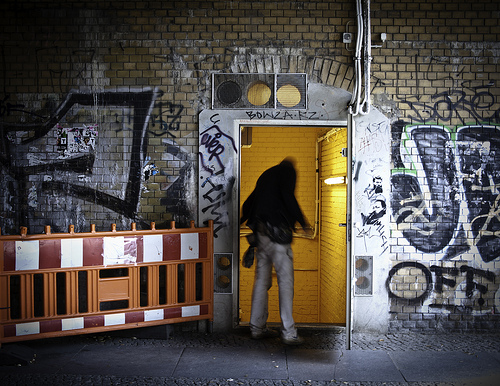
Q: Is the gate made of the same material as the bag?
A: Yes, both the gate and the bag are made of plastic.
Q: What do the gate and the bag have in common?
A: The material, both the gate and the bag are plastic.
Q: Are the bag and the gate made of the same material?
A: Yes, both the bag and the gate are made of plastic.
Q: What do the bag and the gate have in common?
A: The material, both the bag and the gate are plastic.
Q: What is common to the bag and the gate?
A: The material, both the bag and the gate are plastic.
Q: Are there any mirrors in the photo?
A: No, there are no mirrors.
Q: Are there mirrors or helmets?
A: No, there are no mirrors or helmets.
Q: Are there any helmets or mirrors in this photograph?
A: No, there are no mirrors or helmets.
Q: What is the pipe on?
A: The pipe is on the wall.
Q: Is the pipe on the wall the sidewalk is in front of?
A: Yes, the pipe is on the wall.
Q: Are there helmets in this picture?
A: No, there are no helmets.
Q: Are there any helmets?
A: No, there are no helmets.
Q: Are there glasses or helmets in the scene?
A: No, there are no helmets or glasses.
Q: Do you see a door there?
A: Yes, there is a door.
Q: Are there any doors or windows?
A: Yes, there is a door.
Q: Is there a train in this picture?
A: No, there are no trains.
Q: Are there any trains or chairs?
A: No, there are no trains or chairs.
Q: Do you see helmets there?
A: No, there are no helmets.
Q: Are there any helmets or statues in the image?
A: No, there are no helmets or statues.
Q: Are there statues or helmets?
A: No, there are no helmets or statues.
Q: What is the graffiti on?
A: The graffiti is on the wall.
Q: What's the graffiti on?
A: The graffiti is on the wall.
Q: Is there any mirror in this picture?
A: No, there are no mirrors.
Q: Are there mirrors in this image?
A: No, there are no mirrors.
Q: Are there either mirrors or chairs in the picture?
A: No, there are no mirrors or chairs.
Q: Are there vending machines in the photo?
A: No, there are no vending machines.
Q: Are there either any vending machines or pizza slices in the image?
A: No, there are no vending machines or pizza slices.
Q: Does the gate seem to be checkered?
A: Yes, the gate is checkered.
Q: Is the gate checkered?
A: Yes, the gate is checkered.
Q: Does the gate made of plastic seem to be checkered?
A: Yes, the gate is checkered.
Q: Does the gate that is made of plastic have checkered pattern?
A: Yes, the gate is checkered.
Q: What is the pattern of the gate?
A: The gate is checkered.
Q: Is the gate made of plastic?
A: Yes, the gate is made of plastic.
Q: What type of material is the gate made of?
A: The gate is made of plastic.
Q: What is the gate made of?
A: The gate is made of plastic.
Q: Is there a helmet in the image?
A: No, there are no helmets.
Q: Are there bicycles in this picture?
A: No, there are no bicycles.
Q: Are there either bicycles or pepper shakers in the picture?
A: No, there are no bicycles or pepper shakers.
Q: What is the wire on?
A: The wire is on the wall.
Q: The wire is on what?
A: The wire is on the wall.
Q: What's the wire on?
A: The wire is on the wall.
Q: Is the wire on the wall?
A: Yes, the wire is on the wall.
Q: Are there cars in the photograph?
A: No, there are no cars.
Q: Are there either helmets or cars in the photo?
A: No, there are no cars or helmets.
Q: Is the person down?
A: Yes, the person is down.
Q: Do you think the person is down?
A: Yes, the person is down.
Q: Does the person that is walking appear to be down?
A: Yes, the person is down.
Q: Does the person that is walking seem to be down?
A: Yes, the person is down.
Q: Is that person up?
A: No, the person is down.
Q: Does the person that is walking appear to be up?
A: No, the person is down.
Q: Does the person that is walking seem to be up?
A: No, the person is down.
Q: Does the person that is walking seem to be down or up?
A: The person is down.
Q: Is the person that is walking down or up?
A: The person is down.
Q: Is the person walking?
A: Yes, the person is walking.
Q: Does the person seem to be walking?
A: Yes, the person is walking.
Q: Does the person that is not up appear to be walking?
A: Yes, the person is walking.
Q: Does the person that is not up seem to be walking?
A: Yes, the person is walking.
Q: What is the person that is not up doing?
A: The person is walking.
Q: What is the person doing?
A: The person is walking.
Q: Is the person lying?
A: No, the person is walking.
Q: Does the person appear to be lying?
A: No, the person is walking.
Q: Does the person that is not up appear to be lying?
A: No, the person is walking.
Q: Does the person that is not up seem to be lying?
A: No, the person is walking.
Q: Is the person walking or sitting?
A: The person is walking.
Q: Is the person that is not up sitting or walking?
A: The person is walking.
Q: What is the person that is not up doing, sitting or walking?
A: The person is walking.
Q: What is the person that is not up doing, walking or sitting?
A: The person is walking.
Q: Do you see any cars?
A: No, there are no cars.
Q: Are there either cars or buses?
A: No, there are no cars or buses.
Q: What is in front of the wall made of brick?
A: The sidewalk is in front of the wall.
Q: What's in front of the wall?
A: The sidewalk is in front of the wall.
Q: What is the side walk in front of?
A: The side walk is in front of the wall.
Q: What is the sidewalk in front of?
A: The side walk is in front of the wall.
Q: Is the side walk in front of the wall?
A: Yes, the side walk is in front of the wall.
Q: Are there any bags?
A: Yes, there is a bag.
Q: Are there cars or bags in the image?
A: Yes, there is a bag.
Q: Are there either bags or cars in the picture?
A: Yes, there is a bag.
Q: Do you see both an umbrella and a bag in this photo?
A: No, there is a bag but no umbrellas.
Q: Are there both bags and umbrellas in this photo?
A: No, there is a bag but no umbrellas.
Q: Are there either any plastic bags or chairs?
A: Yes, there is a plastic bag.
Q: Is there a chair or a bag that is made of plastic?
A: Yes, the bag is made of plastic.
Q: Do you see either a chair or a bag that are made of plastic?
A: Yes, the bag is made of plastic.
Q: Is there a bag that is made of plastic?
A: Yes, there is a bag that is made of plastic.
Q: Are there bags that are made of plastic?
A: Yes, there is a bag that is made of plastic.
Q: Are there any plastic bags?
A: Yes, there is a bag that is made of plastic.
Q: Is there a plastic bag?
A: Yes, there is a bag that is made of plastic.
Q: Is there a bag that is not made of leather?
A: Yes, there is a bag that is made of plastic.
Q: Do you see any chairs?
A: No, there are no chairs.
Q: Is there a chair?
A: No, there are no chairs.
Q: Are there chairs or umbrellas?
A: No, there are no chairs or umbrellas.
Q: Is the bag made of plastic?
A: Yes, the bag is made of plastic.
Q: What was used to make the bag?
A: The bag is made of plastic.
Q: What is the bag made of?
A: The bag is made of plastic.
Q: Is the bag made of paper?
A: No, the bag is made of plastic.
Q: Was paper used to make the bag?
A: No, the bag is made of plastic.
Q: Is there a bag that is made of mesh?
A: No, there is a bag but it is made of plastic.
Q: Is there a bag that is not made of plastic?
A: No, there is a bag but it is made of plastic.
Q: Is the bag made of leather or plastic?
A: The bag is made of plastic.